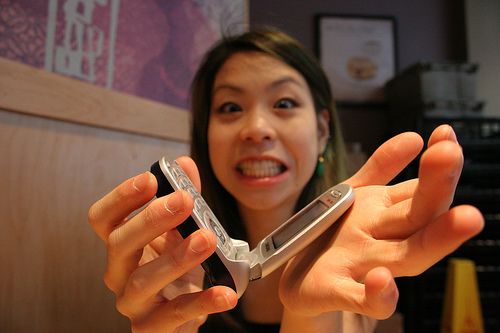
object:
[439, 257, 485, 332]
caution cone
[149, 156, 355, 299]
cell phone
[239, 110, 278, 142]
nose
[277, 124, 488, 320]
hand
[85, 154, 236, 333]
hand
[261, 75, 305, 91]
eyebrows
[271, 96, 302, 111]
eyes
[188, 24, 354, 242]
hair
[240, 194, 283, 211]
chin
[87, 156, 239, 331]
bare finger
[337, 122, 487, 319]
finger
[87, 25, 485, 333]
woman